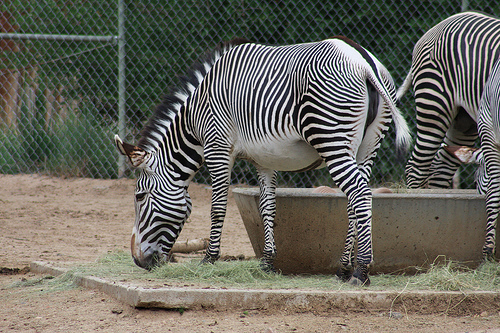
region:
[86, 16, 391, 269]
black and white zebra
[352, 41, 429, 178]
black and white tail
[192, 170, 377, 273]
black and white legs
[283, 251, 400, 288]
zebra has black feet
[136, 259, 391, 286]
green grass is underfoot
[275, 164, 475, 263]
grey tub next to zebras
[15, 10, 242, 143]
chain link fence behind zebras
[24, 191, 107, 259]
brown and dry ground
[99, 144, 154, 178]
black and white ears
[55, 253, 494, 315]
stone platform around trough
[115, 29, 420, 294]
this is a zebra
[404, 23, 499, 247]
this is a zebra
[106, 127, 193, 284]
the head of a zebra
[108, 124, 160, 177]
the ear of a zebra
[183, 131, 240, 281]
the foot of a zebra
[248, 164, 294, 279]
the foot of a zebra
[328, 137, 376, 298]
the foot of a zebra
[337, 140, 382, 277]
the foot of a zebra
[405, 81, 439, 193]
the foot of a zebra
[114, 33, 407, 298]
this is a zebra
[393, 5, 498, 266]
this is a zebra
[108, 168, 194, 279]
the head of a zebra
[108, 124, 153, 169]
the ear of a zebra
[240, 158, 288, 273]
the foot of a zebra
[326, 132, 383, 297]
the foot of a zebra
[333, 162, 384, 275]
the foot of a zebra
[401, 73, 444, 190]
the foot of a zebra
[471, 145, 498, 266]
the foot of a zebra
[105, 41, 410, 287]
this is a black and white zebra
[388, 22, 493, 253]
this is a black and white zebra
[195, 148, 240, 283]
this is a foot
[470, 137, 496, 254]
this is a foot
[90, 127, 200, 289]
head of a zebra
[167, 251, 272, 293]
this is a patch grass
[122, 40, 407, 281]
the zebra is eating.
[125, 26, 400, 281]
the zebra is standing on the grass.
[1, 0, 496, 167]
chain link fence in the background.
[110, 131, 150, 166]
ears on the zebra.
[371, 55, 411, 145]
the tail of the zebra.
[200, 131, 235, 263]
the zebra's left front leg.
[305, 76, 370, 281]
the zebra's left back leg.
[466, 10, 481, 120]
the zebra's black and white stripes.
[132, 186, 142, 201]
zebra has black eyes.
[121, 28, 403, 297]
the zebra is eating the grass.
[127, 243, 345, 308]
Grass on the ground.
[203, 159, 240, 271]
The leg of the zebra.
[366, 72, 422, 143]
tail of the zebra.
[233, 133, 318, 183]
Stomach of the zebra.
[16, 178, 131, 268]
Dirt on the ground.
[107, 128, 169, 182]
Ear of the zebra.